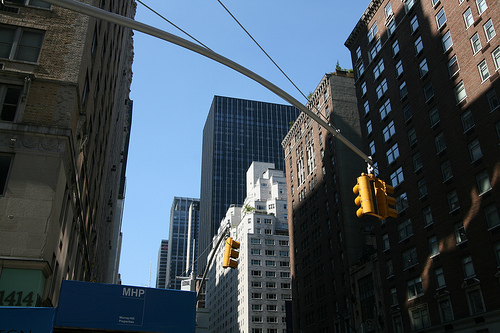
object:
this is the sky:
[144, 52, 206, 136]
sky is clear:
[145, 41, 254, 174]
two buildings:
[147, 195, 209, 333]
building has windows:
[342, 0, 499, 331]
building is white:
[206, 209, 278, 332]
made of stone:
[51, 38, 113, 285]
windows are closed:
[413, 57, 433, 81]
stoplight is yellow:
[218, 235, 243, 271]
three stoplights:
[171, 152, 432, 279]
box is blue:
[54, 276, 199, 332]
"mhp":
[118, 285, 148, 299]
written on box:
[113, 314, 138, 326]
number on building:
[14, 290, 24, 306]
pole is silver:
[50, 0, 371, 163]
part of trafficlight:
[352, 173, 374, 218]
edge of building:
[276, 123, 312, 188]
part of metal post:
[238, 69, 370, 164]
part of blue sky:
[132, 1, 208, 121]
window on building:
[3, 14, 56, 73]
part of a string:
[217, 0, 298, 87]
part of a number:
[20, 290, 36, 306]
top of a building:
[198, 93, 244, 125]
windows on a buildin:
[446, 78, 471, 108]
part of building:
[327, 77, 364, 144]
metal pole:
[35, 0, 374, 174]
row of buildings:
[154, 77, 392, 333]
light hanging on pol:
[342, 160, 405, 230]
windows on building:
[279, 293, 292, 301]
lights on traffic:
[220, 237, 243, 270]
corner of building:
[328, 9, 411, 86]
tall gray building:
[200, 151, 300, 332]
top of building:
[230, 158, 314, 235]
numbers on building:
[0, 289, 6, 306]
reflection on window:
[383, 147, 401, 165]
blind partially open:
[442, 190, 464, 214]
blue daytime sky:
[137, 0, 200, 189]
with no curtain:
[3, 74, 30, 128]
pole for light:
[50, 0, 373, 167]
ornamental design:
[34, 117, 80, 154]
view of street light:
[217, 235, 243, 271]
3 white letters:
[137, 288, 145, 298]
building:
[154, 240, 169, 290]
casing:
[197, 164, 290, 330]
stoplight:
[351, 171, 403, 223]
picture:
[4, 3, 494, 331]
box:
[56, 280, 196, 332]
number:
[22, 289, 33, 306]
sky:
[115, 3, 373, 287]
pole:
[54, 3, 374, 169]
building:
[282, 69, 361, 331]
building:
[203, 160, 292, 331]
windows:
[409, 34, 426, 57]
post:
[43, 0, 375, 166]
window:
[6, 24, 51, 65]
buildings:
[200, 93, 307, 301]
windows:
[263, 248, 276, 256]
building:
[184, 200, 202, 291]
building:
[164, 196, 200, 292]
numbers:
[4, 289, 17, 308]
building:
[94, 8, 131, 321]